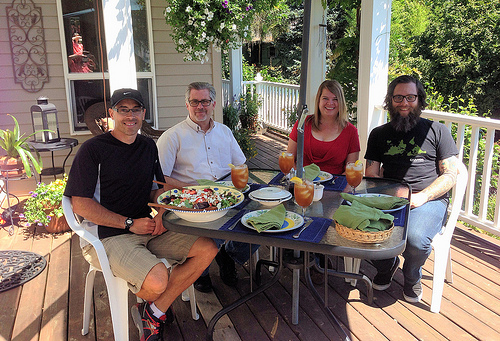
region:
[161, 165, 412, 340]
a square table on the patio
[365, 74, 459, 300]
a bearded man sitting at the table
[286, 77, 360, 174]
a woman sitting at the table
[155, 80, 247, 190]
a middle-aged gentleman sitting at the table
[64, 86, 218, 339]
a young, clean-shaven man at the table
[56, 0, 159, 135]
a window behind the people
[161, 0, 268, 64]
a hanging plant above the table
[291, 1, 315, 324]
a pole going through the table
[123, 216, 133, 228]
a watch on the man's hand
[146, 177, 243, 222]
a large bowl of food on the table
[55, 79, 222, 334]
guy in a black t-shirt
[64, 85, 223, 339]
guy wearing a black cap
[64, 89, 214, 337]
guy wearing a Nike cap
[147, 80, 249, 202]
guy with a grey beard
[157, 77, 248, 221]
guy with a gray beard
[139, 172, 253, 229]
large bowl of salad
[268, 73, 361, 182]
woman in red shirt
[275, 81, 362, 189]
woman with a nice smile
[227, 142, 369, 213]
four glasses of ice tea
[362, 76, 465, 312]
guy with a heavy beard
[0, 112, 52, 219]
potted plant on a stand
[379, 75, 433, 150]
bearded man with glasses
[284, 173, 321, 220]
iced drink with lemon wedge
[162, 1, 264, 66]
purple and white hanging flowers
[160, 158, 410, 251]
table with food and drinks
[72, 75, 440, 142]
people smiling at the camera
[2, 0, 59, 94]
decorative artwork on wall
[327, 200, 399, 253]
basket with green napkins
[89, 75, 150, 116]
black hat with nike logo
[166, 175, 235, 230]
a bowl of fruit salad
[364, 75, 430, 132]
man wearing black glasses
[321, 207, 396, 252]
a basket with green napkins inside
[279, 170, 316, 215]
a glass of iced tea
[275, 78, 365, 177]
a woman wearing a red shirt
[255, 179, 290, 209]
a white bowl covered with white dish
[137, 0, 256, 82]
white flower hanging in a pot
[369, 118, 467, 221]
black and green shirt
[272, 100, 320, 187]
crank for an umbrella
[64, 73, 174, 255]
man in a black shirt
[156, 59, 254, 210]
man in a white button up shirt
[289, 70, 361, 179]
woman in a red shirt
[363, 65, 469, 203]
man in a black shirt with green graphics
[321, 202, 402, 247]
green napkins on top of basket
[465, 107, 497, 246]
white porch railing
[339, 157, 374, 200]
glass of iced tea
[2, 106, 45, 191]
potted plant on stand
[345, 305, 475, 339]
brown wooden decking